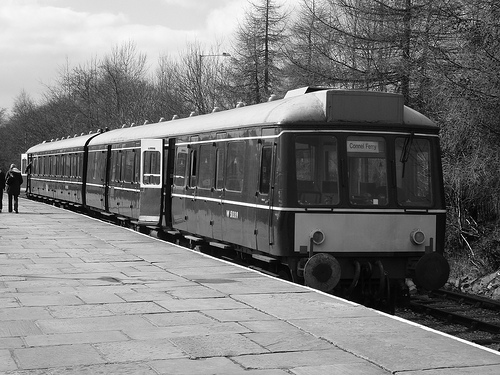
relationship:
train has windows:
[12, 78, 460, 293] [390, 128, 437, 213]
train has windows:
[12, 78, 460, 293] [341, 132, 393, 215]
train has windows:
[12, 78, 460, 293] [286, 129, 342, 210]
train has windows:
[12, 78, 460, 293] [255, 131, 280, 196]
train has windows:
[12, 78, 460, 293] [221, 135, 250, 199]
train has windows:
[12, 78, 460, 293] [212, 135, 228, 194]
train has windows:
[12, 78, 460, 293] [171, 132, 190, 190]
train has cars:
[12, 78, 460, 293] [80, 80, 451, 304]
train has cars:
[12, 78, 460, 293] [11, 124, 95, 213]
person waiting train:
[4, 159, 27, 216] [12, 78, 460, 293]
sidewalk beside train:
[0, 186, 498, 374] [12, 78, 460, 293]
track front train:
[399, 273, 499, 336] [12, 78, 460, 293]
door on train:
[137, 137, 166, 230] [12, 78, 460, 293]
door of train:
[17, 153, 31, 191] [12, 78, 460, 293]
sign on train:
[346, 136, 381, 155] [12, 78, 460, 293]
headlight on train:
[406, 225, 431, 250] [12, 78, 460, 293]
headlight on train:
[310, 229, 328, 246] [12, 78, 460, 293]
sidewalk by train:
[0, 186, 498, 374] [12, 78, 460, 293]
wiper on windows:
[398, 129, 414, 181] [390, 128, 437, 213]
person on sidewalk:
[4, 159, 27, 216] [0, 186, 498, 374]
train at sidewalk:
[12, 78, 460, 293] [0, 186, 498, 374]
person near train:
[4, 159, 27, 216] [12, 78, 460, 293]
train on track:
[12, 78, 460, 293] [399, 273, 499, 336]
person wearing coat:
[4, 159, 27, 216] [3, 167, 26, 199]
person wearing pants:
[4, 159, 27, 216] [7, 187, 21, 213]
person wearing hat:
[4, 159, 27, 216] [10, 166, 23, 177]